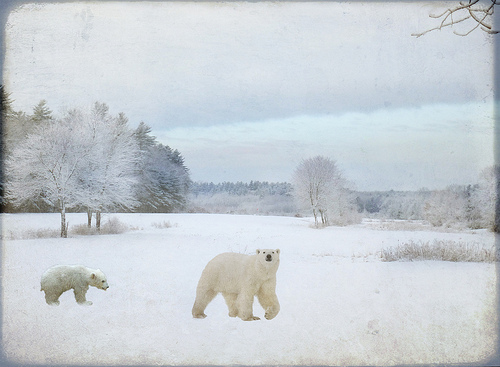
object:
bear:
[191, 248, 279, 320]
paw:
[263, 308, 277, 319]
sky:
[0, 0, 499, 191]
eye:
[263, 251, 266, 255]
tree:
[2, 114, 112, 238]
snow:
[0, 212, 499, 365]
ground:
[0, 212, 499, 366]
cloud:
[143, 101, 499, 191]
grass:
[378, 237, 499, 262]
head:
[256, 248, 282, 269]